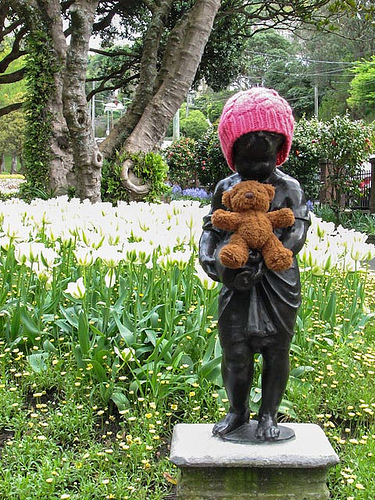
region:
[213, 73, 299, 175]
the beanie is pink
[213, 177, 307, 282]
the stuffed animal is a bear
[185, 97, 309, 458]
the statue is black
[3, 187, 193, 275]
the flower petals are white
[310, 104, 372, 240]
the roses are red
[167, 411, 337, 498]
the statue base is concrete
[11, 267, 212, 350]
the stems of the flowers are green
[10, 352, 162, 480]
the daisies are yellow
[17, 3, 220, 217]
the trees are tall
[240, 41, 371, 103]
the telephone wires are black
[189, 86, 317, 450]
Black statue of child in garden.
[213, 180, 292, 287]
Statue holding brown teddy bear.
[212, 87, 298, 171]
Pink wool cap on statue.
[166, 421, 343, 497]
Concrete base holding statue.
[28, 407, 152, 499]
Yellow flowers growing in garden.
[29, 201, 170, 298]
White flowers growing in garden.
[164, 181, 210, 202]
Blue flowers growing in garden.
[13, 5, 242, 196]
Huge tree inside garden.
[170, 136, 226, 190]
Hedge along edge of garden.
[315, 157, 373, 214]
Metal fence next to garden.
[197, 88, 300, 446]
Statue of a child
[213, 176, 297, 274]
Teddy bear the statue is holding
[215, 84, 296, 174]
Beanie on the statues head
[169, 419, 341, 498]
Concrete pedestal the statue is standing on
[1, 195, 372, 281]
Flowers behind the statue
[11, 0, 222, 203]
Large tree behind the statue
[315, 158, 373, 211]
Fence behind the statue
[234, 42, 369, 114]
Telephone wires in the background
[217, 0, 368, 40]
Tree branches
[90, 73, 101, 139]
Light pole in the background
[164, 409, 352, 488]
Stone pedestal in flowers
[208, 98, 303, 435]
Statue on stone pedestal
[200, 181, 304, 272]
Brown stuffed bear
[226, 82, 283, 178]
Pink knit hat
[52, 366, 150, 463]
Small yellow flowers on the ground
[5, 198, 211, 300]
flower patch behind a statue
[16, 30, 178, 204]
Trees with ivy on them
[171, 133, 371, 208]
Bushes behind a statue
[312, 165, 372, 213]
Metal fence behind flowers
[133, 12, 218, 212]
Large tree behind flowers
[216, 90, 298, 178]
Pink crocheted hat on statue.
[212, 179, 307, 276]
Brown teddy bear being held by statue.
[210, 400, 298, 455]
Feet of statue holding the teddy bear.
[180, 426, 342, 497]
Stone structure child monument is standing on.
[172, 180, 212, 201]
Light purple flowers behind the monument.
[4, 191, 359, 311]
White flowers behind the child statue.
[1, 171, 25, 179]
Small yellow flowers in the background next to the tree.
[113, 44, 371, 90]
Power lines across the screen near the trees.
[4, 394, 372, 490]
Little yellow flowers next to the stone structure holding up the child statue.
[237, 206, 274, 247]
The teddy bear's stomach area.